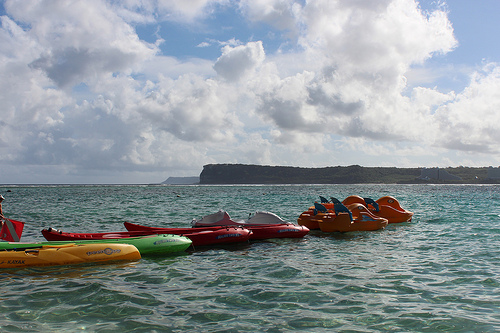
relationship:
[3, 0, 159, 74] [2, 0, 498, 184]
cloud in blue sky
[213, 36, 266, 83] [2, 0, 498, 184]
cloud in blue sky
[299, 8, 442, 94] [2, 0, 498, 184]
clouds in blue sky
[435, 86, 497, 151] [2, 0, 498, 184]
white clouds in blue sky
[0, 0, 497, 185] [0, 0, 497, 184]
clouds in sky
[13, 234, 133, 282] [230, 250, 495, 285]
yellow raft in water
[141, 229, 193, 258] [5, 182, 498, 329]
colored raft in water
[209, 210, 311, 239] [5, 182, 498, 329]
raft in water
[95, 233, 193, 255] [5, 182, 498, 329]
colored raft in water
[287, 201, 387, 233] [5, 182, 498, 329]
raft in water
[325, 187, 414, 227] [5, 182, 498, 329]
raft in water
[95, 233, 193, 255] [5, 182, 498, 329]
colored raft on water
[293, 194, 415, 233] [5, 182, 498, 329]
paddle boats on water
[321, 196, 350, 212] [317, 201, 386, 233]
seats on raft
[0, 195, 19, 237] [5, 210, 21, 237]
person holding material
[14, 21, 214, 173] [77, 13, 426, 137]
clouds in sky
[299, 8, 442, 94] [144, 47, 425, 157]
clouds in sky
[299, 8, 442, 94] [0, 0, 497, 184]
clouds in sky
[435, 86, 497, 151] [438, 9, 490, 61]
white clouds in blue sky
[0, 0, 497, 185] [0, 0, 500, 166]
clouds in blue sky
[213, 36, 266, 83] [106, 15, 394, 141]
cloud in sky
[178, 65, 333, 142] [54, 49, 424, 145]
clouds in sky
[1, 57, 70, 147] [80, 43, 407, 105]
cloud in sky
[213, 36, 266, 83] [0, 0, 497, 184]
cloud in sky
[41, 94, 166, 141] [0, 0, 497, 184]
cloud in sky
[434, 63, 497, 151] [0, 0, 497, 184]
cloud in sky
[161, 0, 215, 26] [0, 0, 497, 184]
cloud in sky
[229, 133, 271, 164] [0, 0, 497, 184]
cloud in sky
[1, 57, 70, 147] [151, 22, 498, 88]
cloud in blue sky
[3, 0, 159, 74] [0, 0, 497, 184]
cloud in sky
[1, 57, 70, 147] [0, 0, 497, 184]
cloud in sky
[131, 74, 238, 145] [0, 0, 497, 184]
cloud in sky